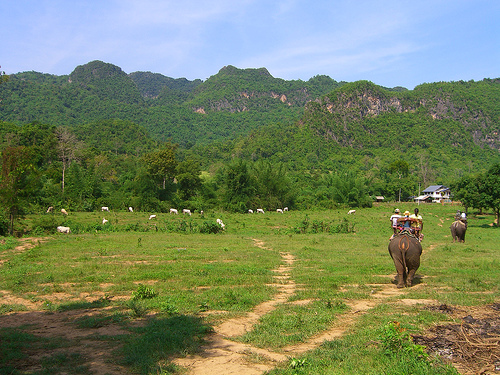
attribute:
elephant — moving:
[388, 233, 423, 291]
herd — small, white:
[44, 204, 357, 235]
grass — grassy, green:
[2, 200, 500, 373]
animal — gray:
[168, 208, 180, 215]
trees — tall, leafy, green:
[3, 119, 418, 208]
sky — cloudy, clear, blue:
[1, 0, 499, 90]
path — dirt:
[208, 234, 301, 339]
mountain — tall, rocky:
[3, 60, 499, 145]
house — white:
[414, 183, 452, 204]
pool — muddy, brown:
[412, 300, 499, 375]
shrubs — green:
[31, 217, 356, 235]